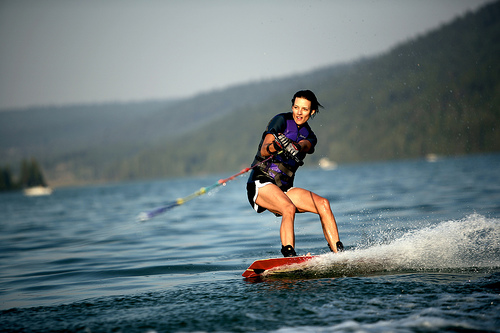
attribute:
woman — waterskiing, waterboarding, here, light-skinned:
[241, 75, 358, 259]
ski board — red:
[229, 241, 381, 293]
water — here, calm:
[345, 214, 490, 276]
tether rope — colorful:
[125, 159, 256, 229]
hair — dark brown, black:
[293, 84, 324, 109]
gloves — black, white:
[271, 136, 304, 158]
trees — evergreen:
[309, 61, 500, 170]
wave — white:
[332, 265, 479, 298]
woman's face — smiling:
[288, 97, 327, 126]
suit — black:
[238, 127, 333, 215]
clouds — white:
[33, 3, 254, 67]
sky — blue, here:
[90, 1, 372, 45]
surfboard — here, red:
[243, 232, 397, 289]